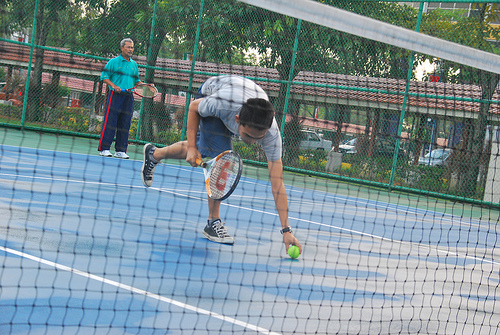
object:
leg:
[98, 96, 120, 150]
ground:
[1, 121, 484, 331]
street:
[290, 142, 476, 191]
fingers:
[294, 241, 302, 254]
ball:
[288, 245, 300, 258]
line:
[0, 249, 188, 310]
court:
[0, 130, 500, 335]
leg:
[155, 140, 200, 161]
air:
[103, 97, 193, 230]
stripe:
[98, 91, 114, 151]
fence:
[0, 2, 499, 138]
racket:
[194, 150, 244, 201]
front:
[133, 149, 325, 258]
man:
[140, 74, 302, 261]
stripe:
[242, 0, 499, 77]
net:
[1, 14, 500, 335]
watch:
[280, 227, 294, 235]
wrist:
[281, 223, 291, 233]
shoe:
[201, 219, 235, 245]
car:
[285, 130, 333, 152]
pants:
[98, 91, 135, 152]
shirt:
[198, 75, 283, 162]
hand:
[186, 148, 203, 167]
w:
[216, 160, 229, 190]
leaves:
[383, 0, 470, 59]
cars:
[335, 138, 411, 164]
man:
[97, 38, 140, 159]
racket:
[118, 84, 159, 98]